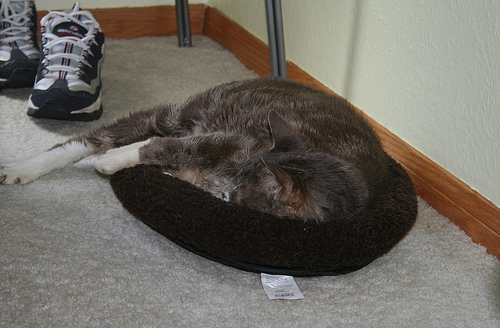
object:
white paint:
[35, 0, 499, 216]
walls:
[33, 0, 499, 211]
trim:
[0, 2, 499, 261]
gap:
[200, 2, 210, 34]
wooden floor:
[83, 0, 290, 85]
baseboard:
[203, 5, 289, 75]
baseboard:
[376, 121, 498, 253]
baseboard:
[82, 5, 199, 37]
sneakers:
[1, 1, 108, 121]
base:
[95, 4, 294, 69]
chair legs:
[129, 1, 314, 93]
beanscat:
[204, 87, 457, 320]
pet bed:
[107, 155, 419, 280]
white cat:
[0, 75, 387, 220]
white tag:
[258, 271, 306, 301]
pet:
[0, 74, 387, 226]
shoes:
[0, 0, 127, 134]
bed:
[96, 137, 438, 296]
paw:
[0, 140, 94, 184]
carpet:
[7, 34, 498, 318]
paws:
[0, 127, 166, 199]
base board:
[29, 4, 496, 278]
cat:
[1, 77, 392, 217]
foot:
[95, 135, 144, 175]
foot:
[2, 140, 96, 188]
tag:
[258, 270, 305, 301]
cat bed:
[109, 137, 420, 278]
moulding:
[33, 2, 483, 252]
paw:
[91, 134, 150, 174]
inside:
[2, 0, 484, 324]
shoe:
[2, 1, 43, 89]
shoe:
[25, 2, 105, 118]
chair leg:
[172, 0, 195, 49]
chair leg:
[262, 0, 287, 77]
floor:
[2, 33, 483, 325]